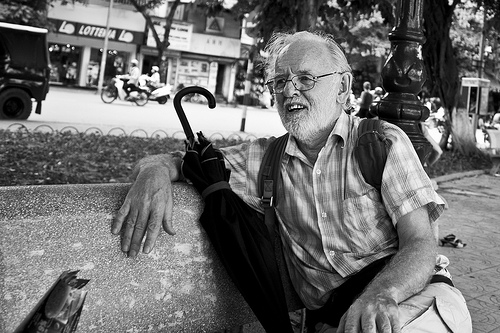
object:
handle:
[172, 86, 216, 139]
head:
[263, 31, 353, 141]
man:
[110, 30, 473, 333]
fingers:
[111, 202, 176, 256]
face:
[272, 43, 335, 138]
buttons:
[321, 212, 327, 217]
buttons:
[316, 169, 321, 174]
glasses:
[264, 72, 341, 95]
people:
[145, 66, 160, 92]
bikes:
[101, 77, 149, 106]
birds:
[441, 234, 467, 248]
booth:
[460, 77, 491, 115]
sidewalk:
[92, 110, 179, 128]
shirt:
[169, 115, 448, 310]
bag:
[11, 266, 92, 333]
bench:
[0, 184, 262, 333]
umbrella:
[172, 85, 292, 331]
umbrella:
[160, 77, 301, 332]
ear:
[336, 72, 353, 104]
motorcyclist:
[136, 73, 171, 104]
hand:
[110, 153, 180, 257]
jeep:
[0, 21, 52, 120]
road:
[58, 105, 132, 125]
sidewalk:
[452, 185, 499, 209]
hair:
[290, 31, 317, 38]